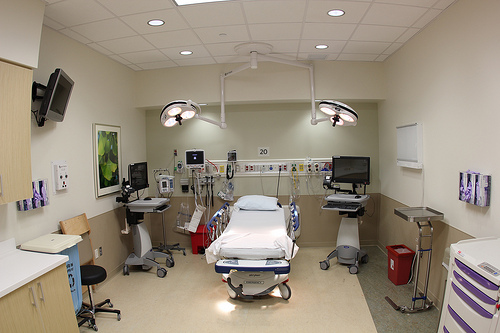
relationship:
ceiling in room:
[244, 5, 345, 75] [7, 28, 459, 330]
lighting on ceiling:
[326, 8, 343, 18] [12, 2, 499, 70]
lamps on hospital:
[161, 102, 196, 129] [0, 0, 498, 332]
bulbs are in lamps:
[316, 40, 333, 52] [161, 102, 196, 129]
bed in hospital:
[203, 193, 303, 302] [0, 0, 498, 332]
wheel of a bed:
[277, 280, 292, 302] [203, 193, 303, 302]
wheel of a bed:
[223, 281, 240, 302] [203, 193, 303, 302]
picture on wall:
[84, 120, 130, 204] [45, 40, 490, 271]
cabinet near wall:
[0, 255, 73, 330] [0, 23, 149, 245]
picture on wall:
[94, 125, 125, 197] [42, 52, 216, 279]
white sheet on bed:
[217, 209, 293, 256] [203, 193, 303, 302]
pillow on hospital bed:
[234, 194, 279, 211] [206, 193, 298, 303]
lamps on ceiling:
[116, 64, 384, 159] [38, 1, 443, 61]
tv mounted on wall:
[31, 66, 77, 127] [37, 25, 160, 93]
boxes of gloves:
[455, 169, 490, 208] [455, 168, 491, 210]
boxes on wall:
[455, 169, 490, 208] [375, 2, 498, 314]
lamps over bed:
[161, 102, 196, 129] [184, 186, 336, 298]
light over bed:
[313, 98, 361, 129] [184, 186, 336, 298]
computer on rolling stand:
[322, 151, 380, 207] [318, 202, 370, 272]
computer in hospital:
[322, 151, 380, 207] [0, 0, 498, 332]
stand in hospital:
[318, 202, 370, 272] [0, 0, 498, 332]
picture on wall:
[94, 125, 125, 197] [0, 23, 149, 245]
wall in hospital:
[0, 23, 149, 245] [0, 0, 498, 332]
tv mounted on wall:
[31, 63, 76, 126] [13, 15, 152, 238]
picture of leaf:
[94, 125, 125, 197] [98, 149, 118, 179]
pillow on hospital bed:
[234, 194, 279, 211] [204, 183, 310, 263]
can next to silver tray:
[386, 245, 414, 287] [392, 205, 446, 223]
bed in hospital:
[203, 191, 303, 306] [0, 0, 498, 332]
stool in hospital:
[83, 259, 125, 326] [0, 0, 498, 332]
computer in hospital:
[324, 132, 378, 239] [0, 0, 498, 332]